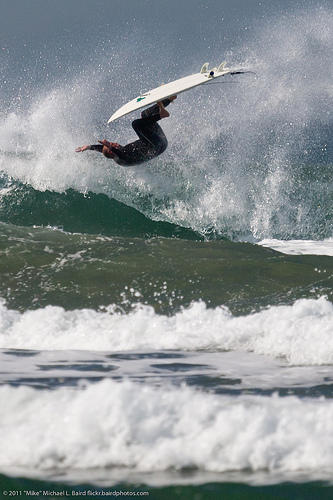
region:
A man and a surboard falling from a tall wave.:
[32, 25, 310, 272]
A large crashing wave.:
[0, 5, 332, 243]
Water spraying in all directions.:
[0, 0, 328, 246]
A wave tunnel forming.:
[0, 157, 248, 242]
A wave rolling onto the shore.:
[0, 379, 328, 493]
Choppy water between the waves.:
[0, 225, 327, 302]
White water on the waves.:
[0, 233, 329, 469]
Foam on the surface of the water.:
[0, 345, 327, 388]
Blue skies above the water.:
[0, 1, 326, 106]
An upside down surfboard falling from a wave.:
[102, 59, 233, 121]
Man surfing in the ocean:
[27, 33, 267, 208]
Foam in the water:
[95, 410, 268, 494]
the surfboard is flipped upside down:
[34, 46, 271, 177]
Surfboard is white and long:
[99, 59, 286, 98]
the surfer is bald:
[55, 125, 211, 156]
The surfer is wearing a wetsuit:
[57, 103, 195, 166]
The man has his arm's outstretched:
[67, 128, 128, 159]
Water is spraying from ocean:
[235, 95, 330, 176]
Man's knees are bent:
[113, 98, 194, 181]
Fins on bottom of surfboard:
[186, 47, 251, 82]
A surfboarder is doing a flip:
[70, 63, 260, 166]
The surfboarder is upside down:
[69, 100, 177, 167]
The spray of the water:
[211, 100, 297, 230]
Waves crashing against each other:
[32, 297, 251, 363]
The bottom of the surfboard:
[106, 61, 268, 122]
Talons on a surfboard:
[198, 61, 235, 79]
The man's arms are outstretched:
[74, 134, 132, 166]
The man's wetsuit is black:
[75, 118, 172, 167]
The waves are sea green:
[67, 249, 217, 296]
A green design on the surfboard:
[134, 95, 149, 102]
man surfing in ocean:
[71, 57, 259, 172]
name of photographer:
[23, 488, 88, 497]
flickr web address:
[85, 487, 153, 499]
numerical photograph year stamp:
[6, 489, 24, 499]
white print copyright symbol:
[0, 488, 10, 497]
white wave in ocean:
[0, 370, 332, 486]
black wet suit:
[87, 96, 177, 168]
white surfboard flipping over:
[93, 56, 261, 125]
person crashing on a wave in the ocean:
[66, 53, 262, 172]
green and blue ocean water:
[0, 147, 329, 499]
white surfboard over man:
[106, 58, 249, 129]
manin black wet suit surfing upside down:
[70, 95, 189, 173]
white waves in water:
[4, 25, 331, 489]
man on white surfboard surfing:
[75, 59, 253, 169]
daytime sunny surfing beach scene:
[8, 7, 332, 495]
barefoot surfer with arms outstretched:
[73, 92, 187, 177]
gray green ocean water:
[8, 213, 331, 305]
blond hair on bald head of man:
[98, 140, 120, 160]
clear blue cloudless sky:
[7, 9, 324, 113]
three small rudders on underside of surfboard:
[199, 60, 224, 79]